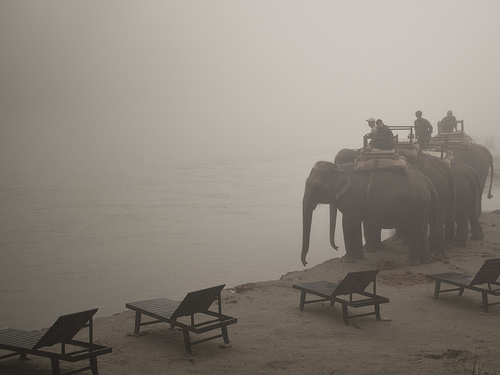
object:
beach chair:
[425, 259, 498, 313]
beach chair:
[292, 268, 387, 328]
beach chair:
[124, 283, 236, 357]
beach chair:
[1, 306, 115, 374]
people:
[356, 115, 398, 157]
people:
[405, 108, 436, 144]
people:
[436, 105, 462, 137]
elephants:
[298, 155, 438, 268]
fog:
[23, 27, 283, 249]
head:
[303, 158, 352, 207]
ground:
[256, 306, 300, 364]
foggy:
[135, 62, 284, 164]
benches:
[125, 283, 241, 359]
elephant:
[300, 151, 438, 264]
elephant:
[389, 137, 491, 247]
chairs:
[0, 255, 500, 373]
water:
[8, 179, 290, 265]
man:
[407, 109, 433, 144]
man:
[437, 109, 460, 135]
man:
[363, 117, 395, 153]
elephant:
[436, 138, 493, 240]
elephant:
[430, 153, 481, 248]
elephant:
[329, 148, 458, 255]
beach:
[1, 207, 498, 374]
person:
[362, 116, 399, 156]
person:
[405, 105, 440, 153]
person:
[437, 104, 466, 142]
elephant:
[359, 145, 485, 246]